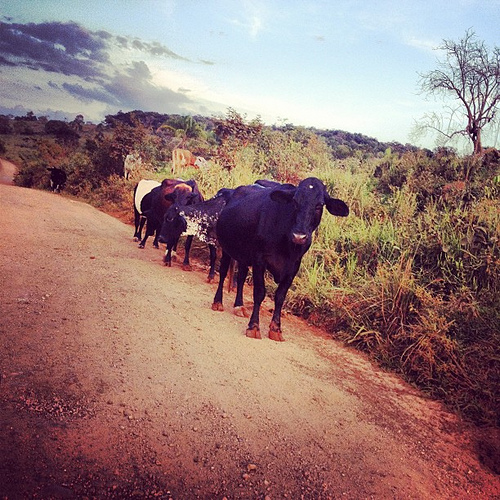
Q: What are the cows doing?
A: Walking down the road.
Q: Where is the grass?
A: Next to the cows.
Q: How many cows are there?
A: Three.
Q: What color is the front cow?
A: Black.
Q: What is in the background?
A: A hill.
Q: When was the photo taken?
A: During the day.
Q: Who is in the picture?
A: The cows.